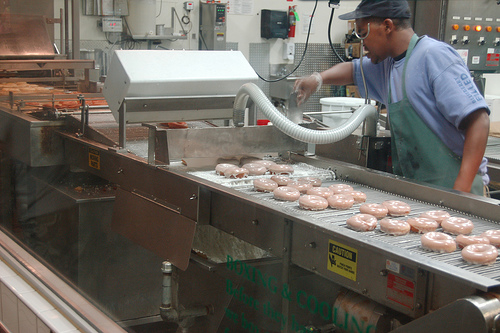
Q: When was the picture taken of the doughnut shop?
A: Early morning.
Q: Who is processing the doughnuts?
A: Male employee.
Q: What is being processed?
A: Doughnuts.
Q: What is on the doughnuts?
A: Glaze.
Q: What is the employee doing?
A: Putting glaze on the doughnuts.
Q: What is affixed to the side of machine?
A: Caution sign.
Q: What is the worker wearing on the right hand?
A: A glove.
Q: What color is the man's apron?
A: Green.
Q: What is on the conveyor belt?
A: Donuts.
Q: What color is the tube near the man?
A: White.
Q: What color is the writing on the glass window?
A: Green.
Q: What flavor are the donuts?
A: Glazed.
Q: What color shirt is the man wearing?
A: Light blue.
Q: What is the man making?
A: Doughnuts.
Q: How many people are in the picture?
A: One.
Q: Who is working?
A: A man.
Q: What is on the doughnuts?
A: Icing.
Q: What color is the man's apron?
A: Green.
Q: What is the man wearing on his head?
A: A hat.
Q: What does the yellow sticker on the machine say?
A: Caution.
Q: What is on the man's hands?
A: Gloves.